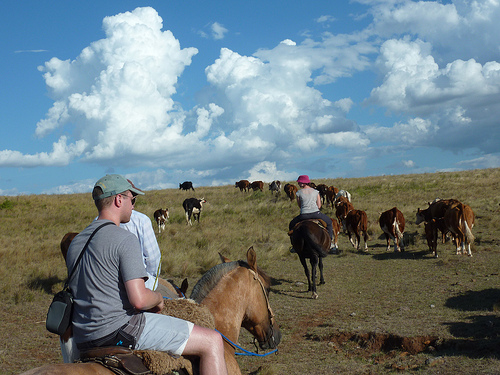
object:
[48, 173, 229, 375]
man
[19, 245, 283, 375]
horse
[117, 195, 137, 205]
sunglasses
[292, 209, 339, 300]
cow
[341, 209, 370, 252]
cow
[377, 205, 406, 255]
cow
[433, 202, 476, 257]
cow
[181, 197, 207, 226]
cow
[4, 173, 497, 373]
field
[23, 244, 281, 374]
brownhorse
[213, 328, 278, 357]
blue reins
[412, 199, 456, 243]
cows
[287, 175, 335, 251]
woman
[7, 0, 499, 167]
sky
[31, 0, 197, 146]
clouds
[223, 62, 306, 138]
puffiest cloud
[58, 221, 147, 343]
t shirt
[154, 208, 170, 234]
cow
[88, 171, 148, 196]
hat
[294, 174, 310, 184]
hat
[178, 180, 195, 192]
black cow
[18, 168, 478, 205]
hill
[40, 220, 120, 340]
satchel